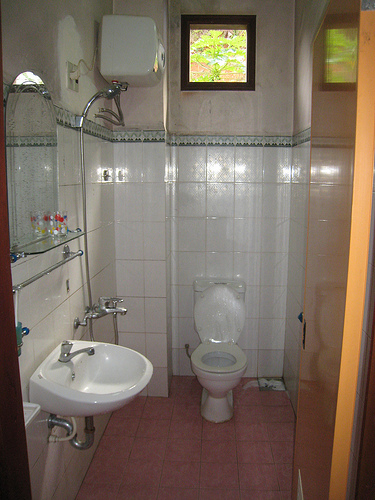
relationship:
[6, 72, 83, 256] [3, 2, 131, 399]
mirror on wall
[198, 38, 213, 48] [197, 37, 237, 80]
leaves on tree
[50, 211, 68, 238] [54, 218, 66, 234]
cup has dots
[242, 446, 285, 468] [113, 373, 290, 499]
tile on floor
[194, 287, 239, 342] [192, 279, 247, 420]
lid on bathroom toilet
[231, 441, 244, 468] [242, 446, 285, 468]
grout between tile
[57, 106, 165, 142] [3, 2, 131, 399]
wall paper on wall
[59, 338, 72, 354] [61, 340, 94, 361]
knob on faucet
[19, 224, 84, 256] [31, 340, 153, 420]
shelf above sink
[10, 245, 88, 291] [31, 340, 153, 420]
towel rack above sink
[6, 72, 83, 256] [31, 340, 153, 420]
mirror above sink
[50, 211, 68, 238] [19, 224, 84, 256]
cup on top of shelf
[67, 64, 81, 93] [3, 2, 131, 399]
outlet on wall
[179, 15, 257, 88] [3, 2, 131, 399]
window on wall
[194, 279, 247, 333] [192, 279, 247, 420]
water tank on bathroom toilet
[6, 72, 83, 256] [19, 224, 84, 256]
mirror above shelf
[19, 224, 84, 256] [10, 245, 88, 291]
shelf above towel rack